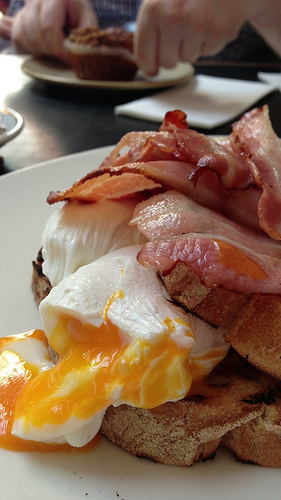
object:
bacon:
[45, 100, 281, 383]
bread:
[29, 242, 281, 467]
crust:
[103, 405, 255, 467]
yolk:
[1, 311, 213, 457]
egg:
[0, 200, 230, 457]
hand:
[10, 0, 96, 60]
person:
[6, 1, 281, 80]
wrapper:
[61, 39, 139, 81]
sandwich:
[1, 98, 281, 472]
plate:
[1, 135, 281, 500]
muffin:
[66, 24, 141, 82]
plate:
[20, 52, 195, 90]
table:
[0, 42, 281, 177]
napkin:
[114, 72, 278, 132]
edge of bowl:
[1, 106, 24, 145]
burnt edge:
[31, 245, 44, 277]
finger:
[134, 0, 158, 77]